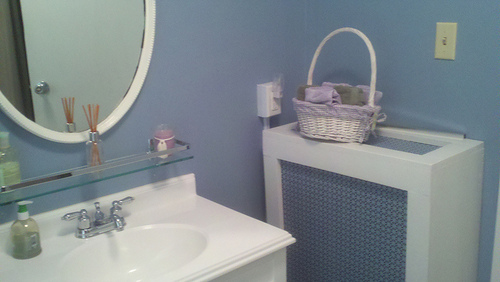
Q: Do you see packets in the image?
A: No, there are no packets.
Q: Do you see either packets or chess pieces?
A: No, there are no packets or chess pieces.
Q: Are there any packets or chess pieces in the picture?
A: No, there are no packets or chess pieces.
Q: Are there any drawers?
A: No, there are no drawers.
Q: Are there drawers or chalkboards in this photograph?
A: No, there are no drawers or chalkboards.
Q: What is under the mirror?
A: The sink is under the mirror.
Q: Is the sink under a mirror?
A: Yes, the sink is under a mirror.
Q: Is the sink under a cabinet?
A: No, the sink is under a mirror.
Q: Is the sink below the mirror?
A: Yes, the sink is below the mirror.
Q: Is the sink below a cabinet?
A: No, the sink is below the mirror.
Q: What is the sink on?
A: The sink is on the counter.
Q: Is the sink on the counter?
A: Yes, the sink is on the counter.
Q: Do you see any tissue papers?
A: No, there are no tissue papers.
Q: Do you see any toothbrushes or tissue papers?
A: No, there are no tissue papers or toothbrushes.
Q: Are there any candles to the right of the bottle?
A: Yes, there is a candle to the right of the bottle.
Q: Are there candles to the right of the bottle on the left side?
A: Yes, there is a candle to the right of the bottle.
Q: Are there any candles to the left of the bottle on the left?
A: No, the candle is to the right of the bottle.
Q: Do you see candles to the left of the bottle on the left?
A: No, the candle is to the right of the bottle.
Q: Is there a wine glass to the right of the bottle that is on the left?
A: No, there is a candle to the right of the bottle.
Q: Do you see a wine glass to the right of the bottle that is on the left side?
A: No, there is a candle to the right of the bottle.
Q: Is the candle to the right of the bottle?
A: Yes, the candle is to the right of the bottle.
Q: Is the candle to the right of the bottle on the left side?
A: Yes, the candle is to the right of the bottle.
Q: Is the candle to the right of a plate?
A: No, the candle is to the right of the bottle.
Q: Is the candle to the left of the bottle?
A: No, the candle is to the right of the bottle.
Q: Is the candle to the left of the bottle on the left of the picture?
A: No, the candle is to the right of the bottle.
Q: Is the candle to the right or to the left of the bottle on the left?
A: The candle is to the right of the bottle.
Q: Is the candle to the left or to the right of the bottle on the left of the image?
A: The candle is to the right of the bottle.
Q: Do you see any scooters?
A: No, there are no scooters.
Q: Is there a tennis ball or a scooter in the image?
A: No, there are no scooters or tennis balls.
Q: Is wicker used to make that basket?
A: Yes, the basket is made of wicker.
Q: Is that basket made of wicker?
A: Yes, the basket is made of wicker.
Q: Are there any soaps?
A: Yes, there is a soap.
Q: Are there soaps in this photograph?
A: Yes, there is a soap.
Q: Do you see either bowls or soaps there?
A: Yes, there is a soap.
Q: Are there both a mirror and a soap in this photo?
A: Yes, there are both a soap and a mirror.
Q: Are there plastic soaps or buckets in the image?
A: Yes, there is a plastic soap.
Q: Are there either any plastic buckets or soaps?
A: Yes, there is a plastic soap.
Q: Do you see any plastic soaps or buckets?
A: Yes, there is a plastic soap.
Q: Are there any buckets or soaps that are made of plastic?
A: Yes, the soap is made of plastic.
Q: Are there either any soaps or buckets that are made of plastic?
A: Yes, the soap is made of plastic.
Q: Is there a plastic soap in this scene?
A: Yes, there is a soap that is made of plastic.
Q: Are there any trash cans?
A: No, there are no trash cans.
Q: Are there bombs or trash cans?
A: No, there are no trash cans or bombs.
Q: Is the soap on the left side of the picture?
A: Yes, the soap is on the left of the image.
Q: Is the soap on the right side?
A: No, the soap is on the left of the image.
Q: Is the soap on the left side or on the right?
A: The soap is on the left of the image.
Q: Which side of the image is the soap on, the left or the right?
A: The soap is on the left of the image.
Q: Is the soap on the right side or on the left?
A: The soap is on the left of the image.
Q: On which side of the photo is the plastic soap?
A: The soap is on the left of the image.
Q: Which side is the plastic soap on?
A: The soap is on the left of the image.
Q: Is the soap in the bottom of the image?
A: Yes, the soap is in the bottom of the image.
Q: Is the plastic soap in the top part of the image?
A: No, the soap is in the bottom of the image.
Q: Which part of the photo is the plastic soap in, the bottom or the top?
A: The soap is in the bottom of the image.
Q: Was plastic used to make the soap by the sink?
A: Yes, the soap is made of plastic.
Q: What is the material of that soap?
A: The soap is made of plastic.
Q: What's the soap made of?
A: The soap is made of plastic.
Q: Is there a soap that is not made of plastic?
A: No, there is a soap but it is made of plastic.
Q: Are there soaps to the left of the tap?
A: Yes, there is a soap to the left of the tap.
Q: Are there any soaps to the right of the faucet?
A: No, the soap is to the left of the faucet.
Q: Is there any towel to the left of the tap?
A: No, there is a soap to the left of the tap.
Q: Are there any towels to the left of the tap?
A: No, there is a soap to the left of the tap.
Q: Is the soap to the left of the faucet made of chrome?
A: Yes, the soap is to the left of the faucet.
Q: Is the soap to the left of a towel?
A: No, the soap is to the left of the faucet.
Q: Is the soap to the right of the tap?
A: No, the soap is to the left of the tap.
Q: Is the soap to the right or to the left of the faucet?
A: The soap is to the left of the faucet.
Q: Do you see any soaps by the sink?
A: Yes, there is a soap by the sink.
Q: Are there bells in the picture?
A: No, there are no bells.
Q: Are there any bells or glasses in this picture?
A: No, there are no bells or glasses.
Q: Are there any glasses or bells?
A: No, there are no bells or glasses.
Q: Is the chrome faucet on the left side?
A: Yes, the tap is on the left of the image.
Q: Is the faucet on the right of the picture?
A: No, the faucet is on the left of the image.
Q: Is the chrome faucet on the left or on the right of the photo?
A: The faucet is on the left of the image.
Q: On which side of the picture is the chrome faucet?
A: The tap is on the left of the image.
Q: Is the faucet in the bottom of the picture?
A: Yes, the faucet is in the bottom of the image.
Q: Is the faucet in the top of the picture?
A: No, the faucet is in the bottom of the image.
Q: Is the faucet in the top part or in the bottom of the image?
A: The faucet is in the bottom of the image.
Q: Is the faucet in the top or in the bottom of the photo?
A: The faucet is in the bottom of the image.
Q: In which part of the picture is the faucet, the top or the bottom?
A: The faucet is in the bottom of the image.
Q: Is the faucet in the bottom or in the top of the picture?
A: The faucet is in the bottom of the image.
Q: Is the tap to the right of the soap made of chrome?
A: Yes, the faucet is made of chrome.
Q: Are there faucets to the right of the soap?
A: Yes, there is a faucet to the right of the soap.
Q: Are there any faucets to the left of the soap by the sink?
A: No, the faucet is to the right of the soap.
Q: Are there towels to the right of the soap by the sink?
A: No, there is a faucet to the right of the soap.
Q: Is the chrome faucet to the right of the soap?
A: Yes, the faucet is to the right of the soap.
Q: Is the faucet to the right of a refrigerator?
A: No, the faucet is to the right of the soap.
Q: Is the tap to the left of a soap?
A: No, the tap is to the right of a soap.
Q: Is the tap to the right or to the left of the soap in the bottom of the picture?
A: The tap is to the right of the soap.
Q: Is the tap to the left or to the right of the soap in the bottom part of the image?
A: The tap is to the right of the soap.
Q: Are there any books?
A: No, there are no books.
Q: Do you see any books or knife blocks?
A: No, there are no books or knife blocks.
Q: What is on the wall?
A: The switch is on the wall.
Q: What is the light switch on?
A: The light switch is on the wall.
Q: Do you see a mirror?
A: Yes, there is a mirror.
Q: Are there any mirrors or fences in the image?
A: Yes, there is a mirror.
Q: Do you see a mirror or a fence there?
A: Yes, there is a mirror.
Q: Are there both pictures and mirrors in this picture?
A: No, there is a mirror but no pictures.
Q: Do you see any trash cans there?
A: No, there are no trash cans.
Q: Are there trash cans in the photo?
A: No, there are no trash cans.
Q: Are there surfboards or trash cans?
A: No, there are no trash cans or surfboards.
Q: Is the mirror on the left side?
A: Yes, the mirror is on the left of the image.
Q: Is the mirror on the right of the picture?
A: No, the mirror is on the left of the image.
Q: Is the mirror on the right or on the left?
A: The mirror is on the left of the image.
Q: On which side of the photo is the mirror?
A: The mirror is on the left of the image.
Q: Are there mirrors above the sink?
A: Yes, there is a mirror above the sink.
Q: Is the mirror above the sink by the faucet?
A: Yes, the mirror is above the sink.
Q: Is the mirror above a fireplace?
A: No, the mirror is above the sink.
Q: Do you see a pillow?
A: No, there are no pillows.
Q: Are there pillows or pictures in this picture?
A: No, there are no pillows or pictures.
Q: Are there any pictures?
A: No, there are no pictures.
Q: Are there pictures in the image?
A: No, there are no pictures.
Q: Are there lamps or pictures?
A: No, there are no pictures or lamps.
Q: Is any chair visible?
A: No, there are no chairs.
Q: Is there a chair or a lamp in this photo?
A: No, there are no chairs or lamps.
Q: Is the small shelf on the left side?
A: Yes, the shelf is on the left of the image.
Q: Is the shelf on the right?
A: No, the shelf is on the left of the image.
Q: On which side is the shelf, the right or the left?
A: The shelf is on the left of the image.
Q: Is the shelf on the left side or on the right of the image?
A: The shelf is on the left of the image.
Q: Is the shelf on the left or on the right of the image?
A: The shelf is on the left of the image.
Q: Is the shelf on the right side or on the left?
A: The shelf is on the left of the image.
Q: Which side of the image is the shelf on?
A: The shelf is on the left of the image.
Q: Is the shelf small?
A: Yes, the shelf is small.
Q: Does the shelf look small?
A: Yes, the shelf is small.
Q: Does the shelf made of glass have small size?
A: Yes, the shelf is small.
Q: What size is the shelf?
A: The shelf is small.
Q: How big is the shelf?
A: The shelf is small.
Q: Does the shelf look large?
A: No, the shelf is small.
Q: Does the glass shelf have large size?
A: No, the shelf is small.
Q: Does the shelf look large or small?
A: The shelf is small.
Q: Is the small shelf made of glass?
A: Yes, the shelf is made of glass.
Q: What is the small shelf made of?
A: The shelf is made of glass.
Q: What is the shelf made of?
A: The shelf is made of glass.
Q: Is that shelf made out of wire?
A: No, the shelf is made of glass.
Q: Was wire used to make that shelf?
A: No, the shelf is made of glass.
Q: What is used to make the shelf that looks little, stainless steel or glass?
A: The shelf is made of glass.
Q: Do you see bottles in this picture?
A: Yes, there is a bottle.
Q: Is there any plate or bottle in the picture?
A: Yes, there is a bottle.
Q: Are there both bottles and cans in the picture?
A: No, there is a bottle but no cans.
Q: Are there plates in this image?
A: No, there are no plates.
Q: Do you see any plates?
A: No, there are no plates.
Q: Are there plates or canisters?
A: No, there are no plates or canisters.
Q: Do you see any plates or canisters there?
A: No, there are no plates or canisters.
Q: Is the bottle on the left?
A: Yes, the bottle is on the left of the image.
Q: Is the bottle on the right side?
A: No, the bottle is on the left of the image.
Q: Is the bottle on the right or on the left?
A: The bottle is on the left of the image.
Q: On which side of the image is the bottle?
A: The bottle is on the left of the image.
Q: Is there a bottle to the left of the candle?
A: Yes, there is a bottle to the left of the candle.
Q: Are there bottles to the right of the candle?
A: No, the bottle is to the left of the candle.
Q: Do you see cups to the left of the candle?
A: No, there is a bottle to the left of the candle.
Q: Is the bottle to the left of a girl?
A: No, the bottle is to the left of the candle.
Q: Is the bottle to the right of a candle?
A: No, the bottle is to the left of a candle.